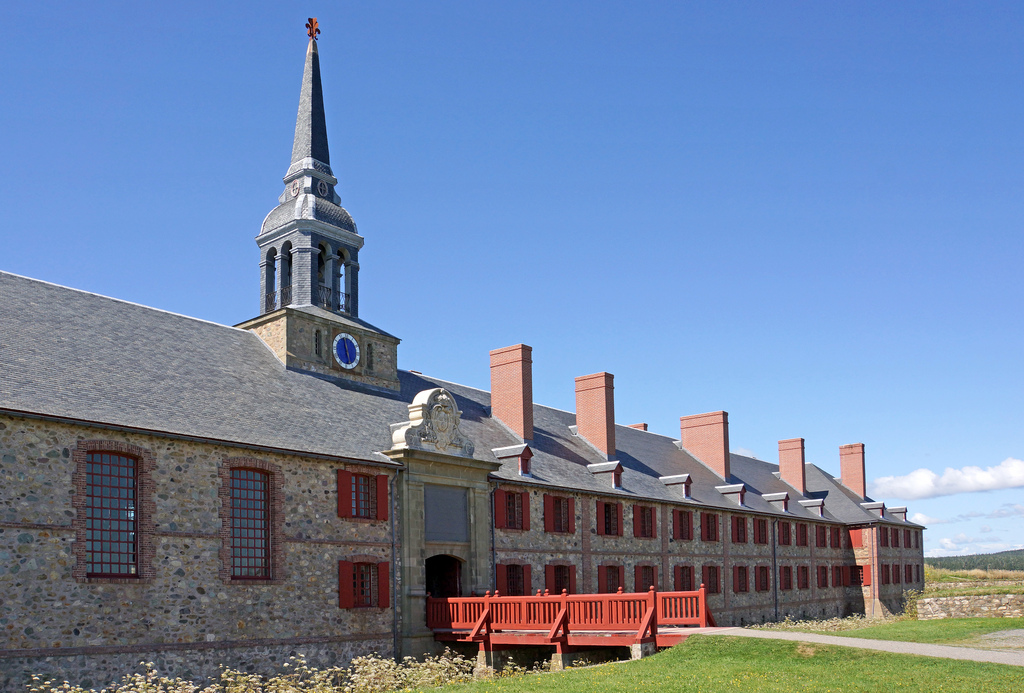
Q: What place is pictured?
A: It is a church.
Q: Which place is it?
A: It is a church.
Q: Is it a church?
A: Yes, it is a church.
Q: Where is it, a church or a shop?
A: It is a church.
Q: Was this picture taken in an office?
A: No, the picture was taken in a church.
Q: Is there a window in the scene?
A: Yes, there is a window.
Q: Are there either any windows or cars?
A: Yes, there is a window.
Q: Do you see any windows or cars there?
A: Yes, there is a window.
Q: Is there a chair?
A: No, there are no chairs.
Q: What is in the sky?
A: The clouds are in the sky.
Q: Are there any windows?
A: Yes, there is a window.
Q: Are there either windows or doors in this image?
A: Yes, there is a window.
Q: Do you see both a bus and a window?
A: No, there is a window but no buses.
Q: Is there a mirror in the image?
A: No, there are no mirrors.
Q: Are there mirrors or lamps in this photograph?
A: No, there are no mirrors or lamps.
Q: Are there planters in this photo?
A: No, there are no planters.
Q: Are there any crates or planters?
A: No, there are no planters or crates.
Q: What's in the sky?
A: The clouds are in the sky.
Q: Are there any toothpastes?
A: No, there are no toothpastes.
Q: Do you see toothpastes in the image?
A: No, there are no toothpastes.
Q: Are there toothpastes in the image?
A: No, there are no toothpastes.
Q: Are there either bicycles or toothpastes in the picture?
A: No, there are no toothpastes or bicycles.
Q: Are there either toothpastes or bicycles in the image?
A: No, there are no toothpastes or bicycles.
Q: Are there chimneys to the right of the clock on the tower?
A: Yes, there is a chimney to the right of the clock.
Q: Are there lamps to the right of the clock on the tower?
A: No, there is a chimney to the right of the clock.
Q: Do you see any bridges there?
A: Yes, there is a bridge.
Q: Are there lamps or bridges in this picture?
A: Yes, there is a bridge.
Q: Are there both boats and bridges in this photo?
A: No, there is a bridge but no boats.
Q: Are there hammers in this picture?
A: No, there are no hammers.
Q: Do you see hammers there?
A: No, there are no hammers.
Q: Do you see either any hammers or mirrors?
A: No, there are no hammers or mirrors.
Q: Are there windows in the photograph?
A: Yes, there is a window.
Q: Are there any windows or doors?
A: Yes, there is a window.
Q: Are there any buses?
A: No, there are no buses.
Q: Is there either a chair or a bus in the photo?
A: No, there are no buses or chairs.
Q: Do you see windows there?
A: Yes, there is a window.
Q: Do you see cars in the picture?
A: No, there are no cars.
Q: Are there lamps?
A: No, there are no lamps.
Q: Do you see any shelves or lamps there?
A: No, there are no lamps or shelves.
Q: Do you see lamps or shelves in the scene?
A: No, there are no lamps or shelves.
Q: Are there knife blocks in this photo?
A: No, there are no knife blocks.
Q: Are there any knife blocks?
A: No, there are no knife blocks.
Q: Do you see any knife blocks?
A: No, there are no knife blocks.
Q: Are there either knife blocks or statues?
A: No, there are no knife blocks or statues.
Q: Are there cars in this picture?
A: No, there are no cars.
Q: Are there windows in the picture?
A: Yes, there are windows.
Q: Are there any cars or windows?
A: Yes, there are windows.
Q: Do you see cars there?
A: No, there are no cars.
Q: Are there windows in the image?
A: Yes, there is a window.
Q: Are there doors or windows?
A: Yes, there is a window.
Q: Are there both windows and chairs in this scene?
A: No, there is a window but no chairs.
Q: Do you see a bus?
A: No, there are no buses.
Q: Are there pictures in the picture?
A: No, there are no pictures.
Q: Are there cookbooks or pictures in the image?
A: No, there are no pictures or cookbooks.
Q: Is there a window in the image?
A: Yes, there is a window.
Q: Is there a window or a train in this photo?
A: Yes, there is a window.